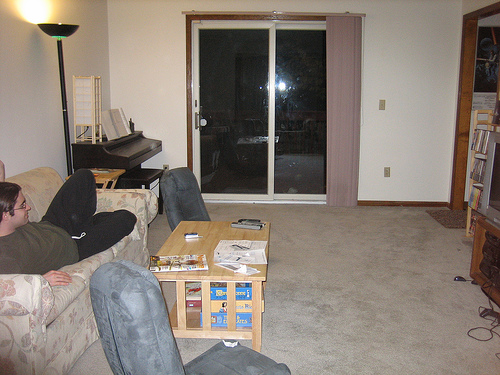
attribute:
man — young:
[2, 172, 138, 270]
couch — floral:
[0, 166, 154, 374]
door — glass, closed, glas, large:
[191, 21, 326, 195]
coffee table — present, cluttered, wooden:
[152, 218, 271, 335]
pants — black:
[44, 170, 136, 257]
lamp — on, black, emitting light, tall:
[41, 22, 78, 176]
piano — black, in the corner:
[74, 128, 165, 185]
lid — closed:
[103, 134, 159, 158]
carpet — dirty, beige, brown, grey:
[77, 193, 500, 368]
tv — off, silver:
[476, 127, 500, 218]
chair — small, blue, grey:
[89, 259, 284, 372]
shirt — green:
[6, 224, 77, 275]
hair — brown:
[2, 183, 17, 214]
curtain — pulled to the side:
[326, 18, 364, 208]